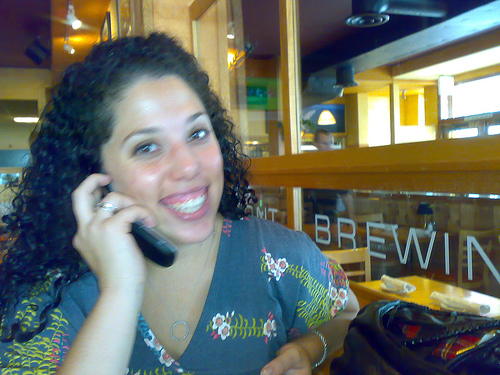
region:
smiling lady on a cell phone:
[12, 22, 299, 354]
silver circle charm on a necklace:
[156, 286, 207, 353]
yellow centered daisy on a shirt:
[210, 300, 291, 349]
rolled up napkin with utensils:
[373, 260, 423, 304]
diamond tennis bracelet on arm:
[301, 322, 343, 373]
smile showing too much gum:
[151, 180, 229, 224]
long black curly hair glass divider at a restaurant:
[317, 195, 481, 272]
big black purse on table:
[358, 290, 490, 370]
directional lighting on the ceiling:
[53, 9, 89, 60]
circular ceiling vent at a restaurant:
[338, 8, 392, 39]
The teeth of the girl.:
[168, 201, 209, 213]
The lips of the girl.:
[157, 188, 217, 219]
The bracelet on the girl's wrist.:
[312, 333, 332, 366]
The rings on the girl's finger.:
[97, 195, 119, 215]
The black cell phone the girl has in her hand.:
[82, 158, 182, 269]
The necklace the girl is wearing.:
[139, 271, 210, 349]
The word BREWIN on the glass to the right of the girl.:
[305, 205, 497, 282]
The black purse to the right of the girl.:
[352, 281, 498, 366]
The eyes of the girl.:
[127, 121, 207, 159]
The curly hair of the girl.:
[15, 51, 266, 301]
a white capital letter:
[313, 208, 330, 244]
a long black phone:
[90, 190, 175, 265]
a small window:
[442, 75, 497, 125]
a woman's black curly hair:
[0, 30, 260, 342]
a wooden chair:
[320, 250, 371, 280]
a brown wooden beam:
[225, 136, 497, 196]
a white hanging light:
[57, 7, 87, 28]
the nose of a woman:
[163, 142, 199, 178]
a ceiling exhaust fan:
[335, 0, 445, 30]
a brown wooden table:
[357, 274, 497, 318]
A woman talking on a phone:
[10, 27, 343, 373]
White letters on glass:
[300, 205, 495, 307]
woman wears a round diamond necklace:
[146, 278, 208, 358]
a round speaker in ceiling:
[338, 11, 390, 35]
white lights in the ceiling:
[66, 8, 85, 66]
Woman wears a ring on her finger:
[97, 191, 122, 216]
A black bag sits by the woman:
[308, 266, 497, 371]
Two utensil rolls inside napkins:
[376, 265, 491, 327]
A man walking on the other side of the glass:
[285, 114, 370, 239]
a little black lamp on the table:
[406, 196, 439, 233]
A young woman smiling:
[8, 44, 382, 373]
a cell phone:
[72, 147, 196, 268]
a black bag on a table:
[337, 280, 497, 372]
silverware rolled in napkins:
[376, 268, 491, 310]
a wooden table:
[342, 250, 497, 343]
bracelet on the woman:
[311, 315, 336, 366]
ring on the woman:
[90, 195, 122, 220]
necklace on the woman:
[138, 236, 219, 356]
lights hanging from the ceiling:
[53, 5, 88, 61]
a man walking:
[298, 125, 350, 227]